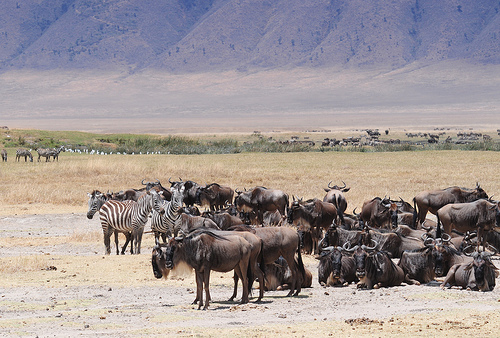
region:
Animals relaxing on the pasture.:
[86, 183, 499, 307]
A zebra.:
[99, 188, 167, 253]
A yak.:
[165, 230, 253, 301]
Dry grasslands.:
[5, 267, 182, 332]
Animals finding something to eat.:
[0, 141, 71, 166]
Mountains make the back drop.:
[6, 2, 497, 78]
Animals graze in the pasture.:
[251, 124, 497, 146]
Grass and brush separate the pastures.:
[68, 127, 273, 148]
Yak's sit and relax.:
[314, 237, 406, 291]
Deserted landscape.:
[8, 70, 483, 115]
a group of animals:
[78, 169, 497, 296]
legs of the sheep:
[191, 282, 227, 317]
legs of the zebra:
[103, 236, 137, 250]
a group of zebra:
[83, 182, 188, 239]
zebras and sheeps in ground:
[76, 161, 494, 316]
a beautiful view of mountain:
[16, 23, 481, 148]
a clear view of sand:
[28, 240, 490, 335]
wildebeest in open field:
[340, 240, 410, 289]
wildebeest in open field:
[442, 243, 499, 299]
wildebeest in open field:
[321, 176, 351, 215]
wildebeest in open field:
[229, 176, 295, 223]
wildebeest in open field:
[391, 235, 448, 286]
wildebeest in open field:
[317, 233, 359, 288]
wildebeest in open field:
[405, 167, 492, 210]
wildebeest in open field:
[187, 175, 239, 210]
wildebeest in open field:
[323, 221, 372, 249]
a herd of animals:
[71, 164, 498, 324]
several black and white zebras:
[79, 176, 196, 258]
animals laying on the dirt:
[313, 234, 498, 298]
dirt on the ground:
[1, 209, 497, 336]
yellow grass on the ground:
[0, 148, 499, 215]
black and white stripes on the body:
[96, 199, 145, 230]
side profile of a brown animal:
[163, 228, 260, 308]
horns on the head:
[336, 235, 383, 252]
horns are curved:
[327, 174, 349, 192]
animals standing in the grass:
[1, 143, 68, 165]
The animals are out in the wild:
[23, 163, 491, 333]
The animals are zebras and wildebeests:
[10, 170, 495, 330]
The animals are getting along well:
[17, 175, 487, 325]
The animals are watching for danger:
[15, 175, 492, 335]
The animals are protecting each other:
[21, 171, 492, 313]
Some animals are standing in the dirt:
[17, 170, 492, 315]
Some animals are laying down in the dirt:
[290, 170, 488, 336]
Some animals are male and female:
[10, 175, 495, 335]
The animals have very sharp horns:
[277, 170, 487, 335]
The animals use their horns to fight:
[291, 170, 496, 332]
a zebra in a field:
[98, 190, 163, 255]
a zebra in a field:
[145, 186, 190, 253]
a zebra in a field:
[86, 190, 134, 256]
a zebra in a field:
[48, 144, 71, 166]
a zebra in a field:
[13, 145, 32, 162]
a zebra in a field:
[1, 147, 8, 159]